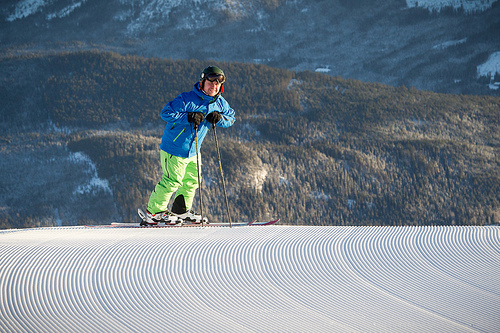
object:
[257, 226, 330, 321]
line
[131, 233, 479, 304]
snow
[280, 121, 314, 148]
tree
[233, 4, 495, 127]
hill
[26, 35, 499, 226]
mountain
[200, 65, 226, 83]
helmet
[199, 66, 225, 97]
head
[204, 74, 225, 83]
goggles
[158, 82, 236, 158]
jacket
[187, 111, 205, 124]
gloves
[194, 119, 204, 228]
pole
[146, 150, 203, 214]
pants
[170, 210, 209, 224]
boots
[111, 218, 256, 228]
skis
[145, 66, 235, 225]
man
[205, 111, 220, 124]
glove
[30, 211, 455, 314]
ground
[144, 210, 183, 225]
boot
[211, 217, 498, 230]
slope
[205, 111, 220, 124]
hand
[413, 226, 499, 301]
ski marks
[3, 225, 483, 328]
ruts